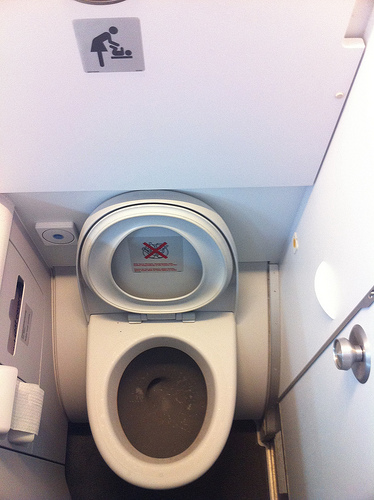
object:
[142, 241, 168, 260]
x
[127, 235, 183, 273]
sign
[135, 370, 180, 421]
dirt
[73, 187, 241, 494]
toilet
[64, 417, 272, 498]
mat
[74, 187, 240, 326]
lid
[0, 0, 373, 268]
wall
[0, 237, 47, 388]
tissue holder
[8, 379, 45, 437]
toilet paper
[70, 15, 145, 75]
symbol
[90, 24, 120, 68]
woman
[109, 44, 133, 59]
baby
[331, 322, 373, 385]
knob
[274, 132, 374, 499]
door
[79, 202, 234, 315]
toilet seat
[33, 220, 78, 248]
sensor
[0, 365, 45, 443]
rack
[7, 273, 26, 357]
slot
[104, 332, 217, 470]
bowl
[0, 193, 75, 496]
wall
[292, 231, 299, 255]
button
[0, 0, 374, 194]
changing table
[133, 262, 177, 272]
lettering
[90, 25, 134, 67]
graphic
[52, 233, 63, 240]
button